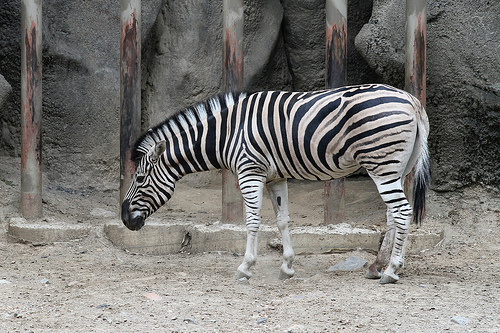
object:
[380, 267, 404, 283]
left foot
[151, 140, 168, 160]
left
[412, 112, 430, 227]
tail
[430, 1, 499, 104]
rock wall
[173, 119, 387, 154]
stripes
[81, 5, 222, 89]
man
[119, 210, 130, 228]
black nose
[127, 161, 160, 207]
face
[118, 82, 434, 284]
animal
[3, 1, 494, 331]
captivity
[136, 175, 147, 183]
eye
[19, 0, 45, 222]
bars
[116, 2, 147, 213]
bars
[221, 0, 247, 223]
bars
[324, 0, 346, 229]
bars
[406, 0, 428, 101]
bars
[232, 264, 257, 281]
foot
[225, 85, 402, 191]
body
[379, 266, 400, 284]
back foot